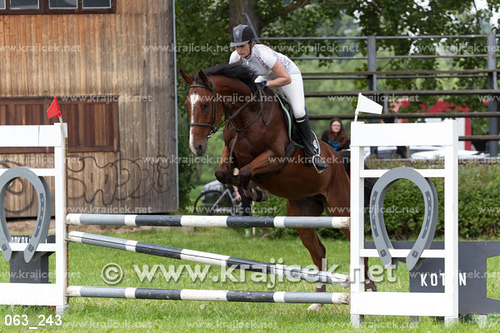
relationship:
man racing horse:
[224, 17, 326, 167] [181, 59, 379, 318]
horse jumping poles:
[178, 66, 378, 311] [62, 206, 353, 233]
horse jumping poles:
[178, 66, 378, 311] [65, 228, 349, 285]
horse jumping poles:
[178, 66, 378, 311] [65, 280, 349, 308]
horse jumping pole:
[181, 59, 379, 318] [67, 209, 351, 236]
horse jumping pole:
[181, 59, 379, 318] [66, 230, 352, 285]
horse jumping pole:
[181, 59, 379, 318] [65, 275, 351, 316]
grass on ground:
[50, 237, 471, 324] [425, 137, 448, 160]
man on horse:
[229, 23, 327, 169] [181, 59, 379, 318]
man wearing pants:
[229, 23, 327, 169] [280, 60, 317, 130]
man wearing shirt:
[229, 23, 327, 169] [225, 40, 302, 79]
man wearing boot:
[229, 23, 327, 169] [305, 153, 329, 169]